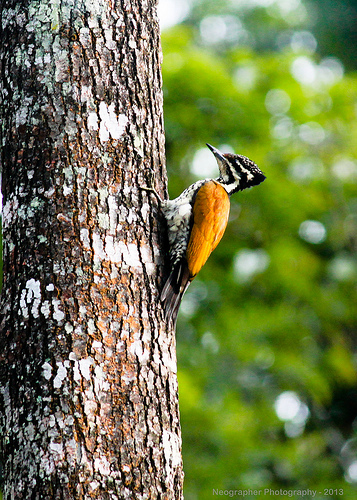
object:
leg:
[136, 169, 165, 205]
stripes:
[242, 160, 260, 182]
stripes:
[223, 164, 236, 185]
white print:
[213, 487, 224, 499]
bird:
[140, 141, 267, 326]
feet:
[138, 167, 162, 202]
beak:
[205, 141, 225, 162]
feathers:
[176, 200, 191, 218]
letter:
[212, 488, 342, 496]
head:
[205, 143, 267, 197]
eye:
[230, 154, 236, 163]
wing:
[186, 179, 231, 278]